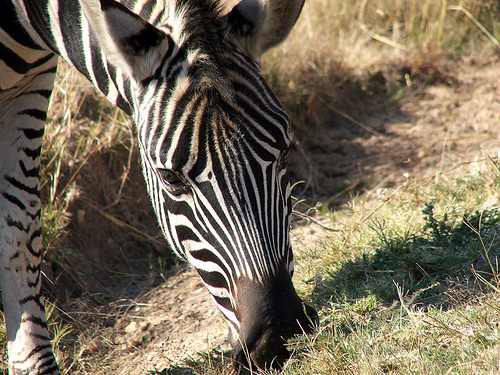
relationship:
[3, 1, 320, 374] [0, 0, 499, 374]
zebra out in a field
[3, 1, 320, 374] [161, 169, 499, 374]
zebra eating some grass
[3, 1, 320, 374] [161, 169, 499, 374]
zebra watching grass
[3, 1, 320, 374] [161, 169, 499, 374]
zebra looking at grass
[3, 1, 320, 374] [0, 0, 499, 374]
zebra in field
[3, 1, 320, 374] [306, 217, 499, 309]
zebra casting a shadow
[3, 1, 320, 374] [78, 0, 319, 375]
zebra has a head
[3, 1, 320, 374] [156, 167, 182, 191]
zebra has an eye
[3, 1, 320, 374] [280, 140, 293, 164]
zebra has an eye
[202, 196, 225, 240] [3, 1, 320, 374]
stripes are on zebra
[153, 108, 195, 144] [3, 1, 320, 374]
stripes are on zebra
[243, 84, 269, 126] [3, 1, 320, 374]
stripes are on zebra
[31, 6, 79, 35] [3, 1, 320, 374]
stripes are on zebra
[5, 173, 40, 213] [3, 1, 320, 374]
stripes are on zebra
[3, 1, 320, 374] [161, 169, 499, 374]
zebra on grass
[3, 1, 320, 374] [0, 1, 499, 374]
zebra on grass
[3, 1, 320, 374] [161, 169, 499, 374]
zebra standing in grass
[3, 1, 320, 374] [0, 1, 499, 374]
zebra standing in grass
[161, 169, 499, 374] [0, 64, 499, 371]
grass on ground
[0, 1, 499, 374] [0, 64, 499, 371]
grass on ground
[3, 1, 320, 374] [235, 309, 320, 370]
zebra has a nose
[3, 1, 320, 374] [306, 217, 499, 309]
zebra has a shadow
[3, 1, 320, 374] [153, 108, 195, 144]
zebra has stripes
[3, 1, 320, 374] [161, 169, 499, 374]
zebra eating grass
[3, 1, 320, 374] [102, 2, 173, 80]
zebra has an ear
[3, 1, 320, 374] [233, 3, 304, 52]
zebra has an ear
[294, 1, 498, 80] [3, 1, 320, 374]
grass behind zebra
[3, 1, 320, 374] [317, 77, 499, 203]
zebra in sunshine